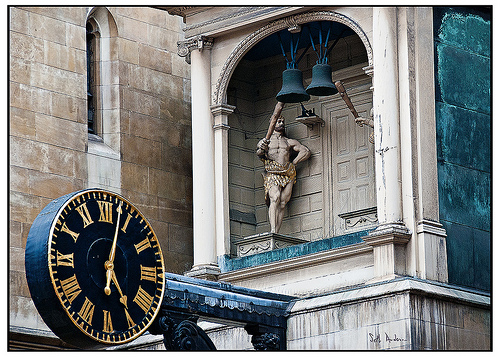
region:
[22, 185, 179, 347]
gold and black clock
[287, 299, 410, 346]
black marks on the building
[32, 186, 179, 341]
roman numerals arond the circumference of the clock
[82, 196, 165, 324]
two gold clock hands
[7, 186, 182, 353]
clock indicating it's a little past 5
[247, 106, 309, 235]
statue of a man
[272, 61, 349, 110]
two black bells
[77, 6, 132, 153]
narrow window on the side of the building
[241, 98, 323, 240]
statue is not wearing a shirt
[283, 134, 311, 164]
arm is bent at the elbow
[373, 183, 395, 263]
part of a pi;;ar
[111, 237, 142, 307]
part of a clock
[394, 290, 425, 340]
[art of a line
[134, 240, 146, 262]
part of a roman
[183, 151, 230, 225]
part of a pillar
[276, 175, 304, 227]
part of a thigh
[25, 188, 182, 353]
black and gold clock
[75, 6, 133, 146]
skinny window on the side of the building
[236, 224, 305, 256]
small pedestal under the statue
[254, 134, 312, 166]
statue is not wearing a shirt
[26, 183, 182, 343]
roman numerals along the circumference of the clock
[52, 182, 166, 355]
this is a clock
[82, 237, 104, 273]
the clock is black in color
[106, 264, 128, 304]
this is the hour hand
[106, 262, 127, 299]
the hour hand is brown in color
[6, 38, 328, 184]
this is a building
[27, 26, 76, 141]
this is a wall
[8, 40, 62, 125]
the wall is brown in color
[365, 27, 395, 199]
this is a pillar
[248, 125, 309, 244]
this is a statue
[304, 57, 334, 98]
this is a bell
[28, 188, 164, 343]
A clock by the statue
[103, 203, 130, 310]
Hands on the clock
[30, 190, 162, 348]
Roman numerals on the clock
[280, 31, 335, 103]
Bells above the statue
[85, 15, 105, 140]
A window on the building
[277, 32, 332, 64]
Ropes connected to the bells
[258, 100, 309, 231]
A statue near the wall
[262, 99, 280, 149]
A weapon the right hand of the statue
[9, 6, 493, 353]
A building with statues and clocks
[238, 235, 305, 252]
A pedestal beneath the statue